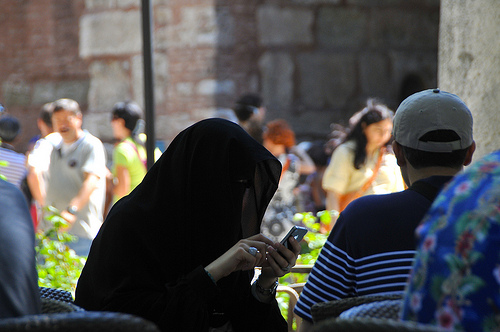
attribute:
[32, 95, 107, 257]
person — standing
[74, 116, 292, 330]
clothing — black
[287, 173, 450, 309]
shirt — striped, blue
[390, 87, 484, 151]
hat — white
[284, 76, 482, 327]
man — sitting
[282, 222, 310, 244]
cellphone — iphone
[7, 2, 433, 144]
wall — brick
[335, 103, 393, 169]
hair — black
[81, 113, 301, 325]
person — texting, completely covered u, muslim